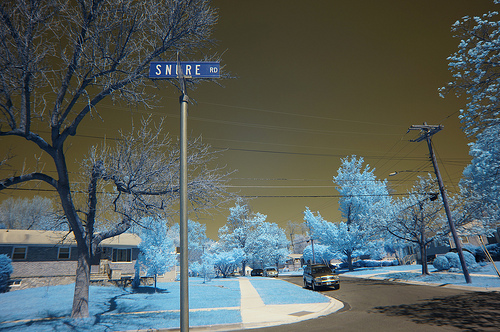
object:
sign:
[151, 48, 226, 97]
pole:
[147, 45, 223, 328]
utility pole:
[399, 117, 476, 285]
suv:
[300, 267, 349, 292]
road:
[353, 284, 427, 326]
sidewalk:
[232, 272, 266, 331]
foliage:
[47, 31, 189, 137]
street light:
[383, 161, 406, 181]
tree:
[343, 163, 383, 209]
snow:
[373, 202, 374, 204]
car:
[263, 264, 281, 279]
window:
[52, 243, 78, 261]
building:
[0, 224, 151, 293]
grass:
[191, 284, 252, 324]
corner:
[236, 293, 300, 329]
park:
[295, 241, 462, 325]